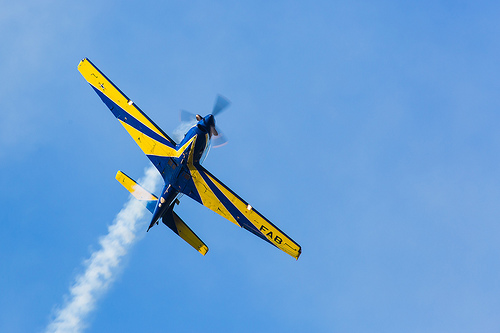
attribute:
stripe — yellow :
[116, 119, 196, 159]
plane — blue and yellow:
[74, 55, 301, 259]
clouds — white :
[44, 166, 166, 330]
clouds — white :
[242, 2, 497, 186]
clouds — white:
[61, 201, 140, 310]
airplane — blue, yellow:
[76, 57, 301, 259]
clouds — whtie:
[311, 55, 378, 140]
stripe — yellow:
[188, 166, 308, 260]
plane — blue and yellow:
[48, 44, 328, 274]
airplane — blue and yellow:
[67, 50, 308, 278]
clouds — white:
[234, 110, 466, 230]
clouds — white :
[30, 152, 155, 315]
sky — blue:
[1, 0, 496, 330]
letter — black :
[256, 218, 268, 236]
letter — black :
[263, 222, 276, 239]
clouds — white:
[10, 150, 174, 330]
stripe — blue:
[191, 162, 271, 244]